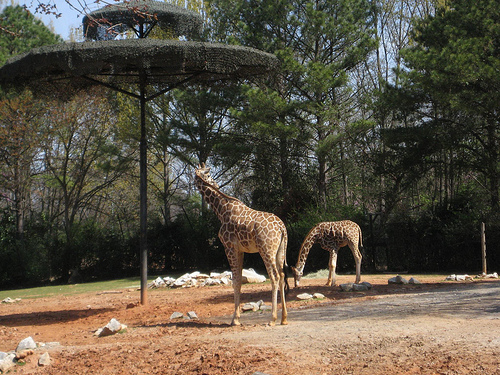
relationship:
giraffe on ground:
[173, 143, 315, 349] [3, 273, 500, 375]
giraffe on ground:
[291, 219, 364, 285] [3, 273, 500, 375]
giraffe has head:
[291, 219, 364, 285] [285, 259, 305, 294]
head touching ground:
[285, 259, 305, 294] [3, 273, 500, 375]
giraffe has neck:
[173, 143, 315, 349] [189, 174, 238, 220]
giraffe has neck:
[291, 219, 364, 285] [295, 223, 321, 273]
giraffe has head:
[173, 143, 315, 349] [181, 157, 226, 199]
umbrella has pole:
[0, 2, 275, 312] [126, 76, 161, 312]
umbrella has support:
[0, 2, 275, 312] [145, 71, 205, 111]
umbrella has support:
[0, 2, 275, 312] [76, 76, 140, 107]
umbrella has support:
[0, 2, 275, 312] [121, 16, 167, 41]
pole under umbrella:
[126, 76, 161, 312] [0, 2, 275, 312]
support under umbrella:
[145, 71, 205, 111] [0, 2, 275, 312]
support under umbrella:
[76, 76, 140, 107] [0, 2, 275, 312]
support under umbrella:
[121, 16, 167, 41] [0, 2, 275, 312]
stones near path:
[91, 312, 136, 345] [198, 273, 499, 365]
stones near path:
[160, 303, 205, 330] [198, 273, 499, 365]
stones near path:
[237, 292, 275, 321] [198, 273, 499, 365]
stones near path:
[290, 289, 332, 314] [198, 273, 499, 365]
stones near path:
[335, 275, 376, 302] [198, 273, 499, 365]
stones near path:
[384, 270, 420, 292] [198, 273, 499, 365]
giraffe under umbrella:
[173, 143, 315, 349] [0, 2, 275, 312]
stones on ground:
[91, 312, 136, 345] [3, 273, 500, 375]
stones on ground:
[160, 303, 205, 330] [3, 273, 500, 375]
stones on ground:
[237, 292, 275, 321] [3, 273, 500, 375]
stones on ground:
[290, 289, 332, 314] [3, 273, 500, 375]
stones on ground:
[335, 275, 376, 302] [3, 273, 500, 375]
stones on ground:
[384, 270, 420, 292] [3, 273, 500, 375]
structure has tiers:
[10, 20, 274, 74] [7, 2, 289, 67]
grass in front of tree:
[19, 279, 151, 295] [23, 97, 62, 235]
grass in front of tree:
[19, 279, 151, 295] [66, 114, 125, 247]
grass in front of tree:
[19, 279, 151, 295] [185, 78, 254, 228]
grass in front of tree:
[19, 279, 151, 295] [297, 52, 365, 220]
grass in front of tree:
[19, 279, 151, 295] [406, 57, 494, 194]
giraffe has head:
[291, 219, 364, 285] [291, 261, 306, 291]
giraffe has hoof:
[193, 161, 289, 328] [267, 322, 278, 329]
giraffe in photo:
[291, 218, 363, 285] [2, 1, 495, 371]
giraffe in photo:
[193, 161, 289, 328] [2, 1, 495, 371]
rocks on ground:
[166, 257, 227, 289] [182, 289, 222, 308]